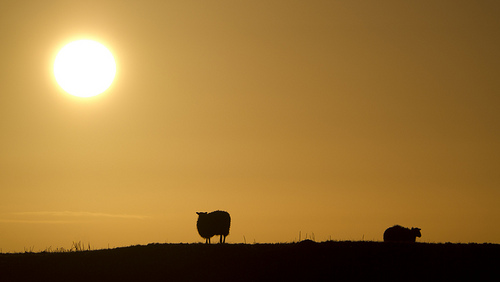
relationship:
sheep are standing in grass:
[195, 210, 231, 244] [0, 230, 498, 280]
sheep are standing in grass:
[383, 224, 421, 242] [0, 230, 498, 280]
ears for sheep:
[411, 225, 421, 230] [383, 224, 421, 242]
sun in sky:
[42, 30, 124, 107] [3, 0, 498, 253]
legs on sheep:
[202, 231, 228, 251] [195, 210, 231, 244]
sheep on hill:
[193, 206, 232, 246] [7, 239, 498, 277]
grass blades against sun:
[13, 230, 415, 256] [51, 39, 118, 98]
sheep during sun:
[195, 210, 231, 244] [51, 39, 118, 98]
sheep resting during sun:
[380, 222, 428, 249] [51, 39, 118, 98]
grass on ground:
[32, 239, 101, 260] [0, 239, 497, 280]